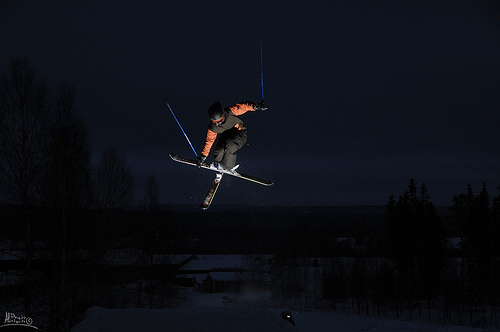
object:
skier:
[192, 100, 270, 170]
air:
[2, 3, 497, 331]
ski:
[168, 151, 274, 186]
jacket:
[204, 103, 261, 157]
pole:
[258, 38, 266, 107]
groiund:
[1, 273, 499, 332]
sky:
[3, 4, 499, 196]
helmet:
[206, 102, 225, 123]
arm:
[227, 101, 262, 115]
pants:
[212, 131, 249, 170]